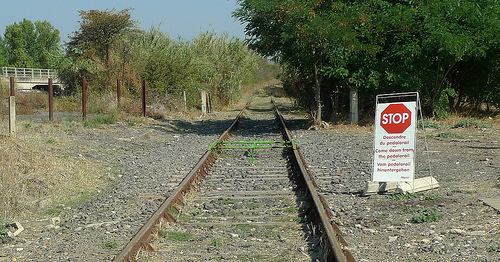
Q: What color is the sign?
A: White.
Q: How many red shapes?
A: One.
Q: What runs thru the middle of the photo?
A: Tracks.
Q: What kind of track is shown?
A: Railroad track.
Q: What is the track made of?
A: Metal.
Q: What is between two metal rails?
A: Wood.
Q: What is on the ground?
A: Rocks and sand.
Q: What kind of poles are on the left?
A: Wooden.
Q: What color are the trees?
A: Green.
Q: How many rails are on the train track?
A: Two.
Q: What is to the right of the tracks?
A: A sign.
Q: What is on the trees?
A: Leaves.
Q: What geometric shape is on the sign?
A: Octagon.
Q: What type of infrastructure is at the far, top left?
A: Bridge.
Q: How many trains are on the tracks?
A: None.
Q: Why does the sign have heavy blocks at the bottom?
A: To weight it down.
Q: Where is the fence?
A: Along the left side of the tracks.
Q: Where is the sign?
A: Next to the railroad tracks.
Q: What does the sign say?
A: Stop.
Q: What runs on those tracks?
A: A train.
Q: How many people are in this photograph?
A: Zero.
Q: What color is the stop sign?
A: Red.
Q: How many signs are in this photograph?
A: One.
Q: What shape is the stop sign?
A: An octagon.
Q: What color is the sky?
A: Blue.